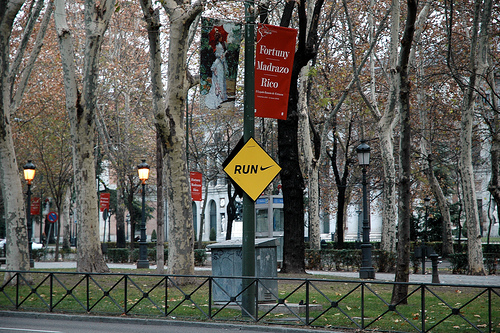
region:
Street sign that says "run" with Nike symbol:
[217, 132, 286, 204]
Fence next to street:
[8, 264, 242, 331]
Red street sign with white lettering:
[246, 40, 299, 134]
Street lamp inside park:
[131, 152, 154, 273]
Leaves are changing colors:
[11, 43, 73, 163]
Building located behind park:
[205, 148, 230, 246]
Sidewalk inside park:
[441, 267, 498, 290]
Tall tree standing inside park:
[135, 47, 210, 292]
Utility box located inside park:
[203, 234, 279, 310]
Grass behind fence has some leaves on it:
[108, 282, 202, 314]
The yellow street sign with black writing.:
[228, 137, 280, 199]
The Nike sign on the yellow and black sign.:
[258, 162, 275, 175]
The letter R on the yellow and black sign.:
[232, 159, 244, 171]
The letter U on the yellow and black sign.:
[242, 162, 252, 177]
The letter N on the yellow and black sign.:
[250, 163, 257, 176]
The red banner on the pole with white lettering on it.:
[259, 20, 292, 112]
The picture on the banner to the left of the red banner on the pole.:
[196, 13, 239, 118]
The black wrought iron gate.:
[3, 281, 492, 331]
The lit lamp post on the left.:
[16, 152, 73, 287]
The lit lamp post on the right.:
[128, 147, 167, 259]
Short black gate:
[137, 275, 301, 327]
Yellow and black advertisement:
[220, 130, 292, 219]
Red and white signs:
[202, 16, 295, 119]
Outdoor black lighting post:
[121, 154, 159, 271]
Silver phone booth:
[258, 191, 283, 252]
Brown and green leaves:
[38, 65, 70, 173]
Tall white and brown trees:
[326, 58, 495, 274]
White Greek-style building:
[207, 186, 224, 231]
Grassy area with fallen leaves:
[401, 300, 421, 325]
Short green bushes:
[308, 244, 356, 272]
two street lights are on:
[19, 152, 153, 195]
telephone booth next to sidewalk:
[228, 183, 335, 279]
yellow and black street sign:
[222, 122, 323, 225]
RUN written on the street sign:
[222, 123, 306, 239]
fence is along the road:
[48, 266, 334, 331]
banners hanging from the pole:
[213, 15, 311, 133]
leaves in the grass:
[335, 291, 470, 331]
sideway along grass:
[239, 217, 478, 290]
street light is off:
[351, 136, 407, 251]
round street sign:
[25, 205, 73, 249]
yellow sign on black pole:
[221, 133, 291, 205]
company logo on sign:
[259, 159, 274, 176]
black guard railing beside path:
[30, 270, 185, 322]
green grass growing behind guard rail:
[95, 279, 183, 310]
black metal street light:
[350, 126, 388, 280]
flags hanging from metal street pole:
[189, 17, 307, 124]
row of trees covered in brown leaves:
[0, 0, 192, 133]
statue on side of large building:
[212, 206, 228, 240]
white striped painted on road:
[0, 314, 70, 331]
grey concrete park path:
[444, 271, 499, 285]